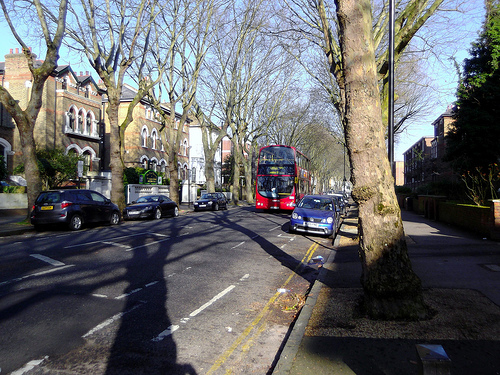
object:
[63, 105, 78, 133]
window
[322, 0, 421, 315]
tree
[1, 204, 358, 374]
shadow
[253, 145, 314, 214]
bus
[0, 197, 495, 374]
road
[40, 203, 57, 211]
license plate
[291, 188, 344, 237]
car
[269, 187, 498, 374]
sidewalk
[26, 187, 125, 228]
car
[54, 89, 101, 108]
stripe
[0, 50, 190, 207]
building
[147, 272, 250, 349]
line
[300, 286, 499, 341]
gravel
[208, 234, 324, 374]
line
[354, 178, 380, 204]
moss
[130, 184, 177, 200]
fence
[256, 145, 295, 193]
windshield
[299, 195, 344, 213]
windshield